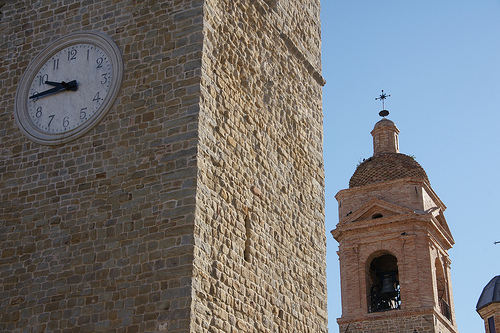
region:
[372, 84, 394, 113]
Metal cross with star shape at center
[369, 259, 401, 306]
Large black metal bell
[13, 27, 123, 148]
Clock with the time saying 9:44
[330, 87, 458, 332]
Bell tower made out of brick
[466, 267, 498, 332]
Brick building with a black roof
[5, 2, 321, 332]
Brick wall with clock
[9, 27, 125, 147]
Clock with white face and black hands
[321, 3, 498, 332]
Clear blue sky with no clouds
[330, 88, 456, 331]
Brick tower with arched windows at top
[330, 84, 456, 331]
Pale brick building with rounded top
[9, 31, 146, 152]
The time is 9:45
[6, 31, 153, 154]
the clock is a dirty cream color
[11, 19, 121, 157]
the hands of the clock are black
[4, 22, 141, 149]
there is a stone ring around the clock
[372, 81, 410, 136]
the tower has a weather vane on top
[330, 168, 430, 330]
the tower is made of tan colored stone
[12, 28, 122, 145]
clock saying 9:45 am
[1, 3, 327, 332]
a tower of irregular brick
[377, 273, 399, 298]
a bell in the bell tower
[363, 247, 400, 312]
an arched opening in the bell tower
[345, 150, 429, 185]
a domed roof on the tower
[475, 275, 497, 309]
part of a domed roof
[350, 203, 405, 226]
a triangle on the bell tower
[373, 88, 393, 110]
a weather vane on the top of the tower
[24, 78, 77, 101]
the minute hand of the clock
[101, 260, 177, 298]
Small bricks on the wall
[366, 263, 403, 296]
A black bell inside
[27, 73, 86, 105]
BLack hands of the clock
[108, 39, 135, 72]
Edge of the stone clock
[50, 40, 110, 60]
Black dots at the top of the numbers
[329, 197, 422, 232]
A hole at the center of the triangle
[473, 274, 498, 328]
An edge of the roof of a tower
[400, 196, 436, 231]
Red stones formed into wall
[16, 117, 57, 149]
Edge of a round clock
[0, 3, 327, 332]
A stone clock tower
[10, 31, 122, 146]
A clock on the clock tower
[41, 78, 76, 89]
Black hour hand of the clock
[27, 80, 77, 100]
Black minute hand of the clock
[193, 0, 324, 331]
One side of the stone clock tower that is facing the sun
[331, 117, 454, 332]
Another tower behind the clock tower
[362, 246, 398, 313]
An arched window on the tower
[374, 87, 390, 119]
Lightning guard on top of the tower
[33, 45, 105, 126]
English numerals on the white clock face